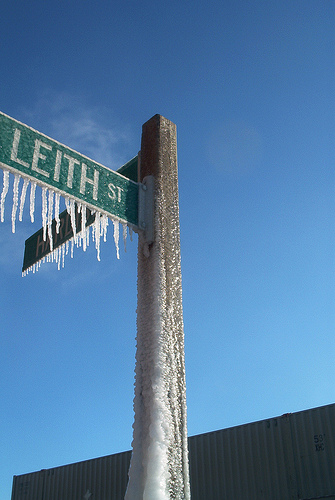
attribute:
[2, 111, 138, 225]
sign — green, streetsign, metal, frozen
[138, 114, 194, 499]
pole — steel, iced, tall, rusted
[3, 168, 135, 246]
ice — hanging, sickled, thick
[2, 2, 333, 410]
sky — clear blue, hazy, blue, cloudless, very blue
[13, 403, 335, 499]
building — metal, gray, beige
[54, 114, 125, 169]
clouds — few, small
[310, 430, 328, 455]
writing — numbers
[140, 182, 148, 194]
bolts — small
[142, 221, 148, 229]
screw — small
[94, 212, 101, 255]
icecle — hanging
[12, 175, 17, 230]
icicle — hanging